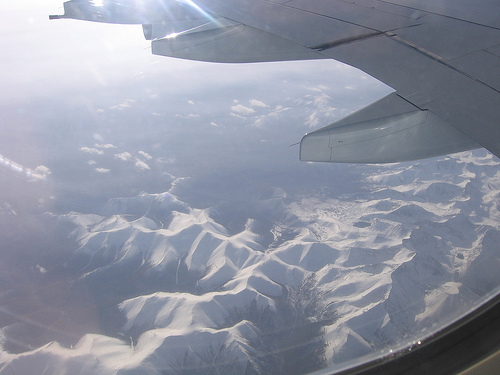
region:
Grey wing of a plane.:
[62, 2, 498, 164]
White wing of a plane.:
[52, 0, 499, 165]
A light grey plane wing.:
[50, 2, 498, 168]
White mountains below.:
[11, 143, 497, 373]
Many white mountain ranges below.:
[27, 128, 489, 373]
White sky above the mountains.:
[2, 2, 178, 92]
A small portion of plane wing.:
[45, 2, 498, 163]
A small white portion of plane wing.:
[47, 3, 498, 167]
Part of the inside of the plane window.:
[349, 295, 499, 372]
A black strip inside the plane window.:
[325, 295, 499, 373]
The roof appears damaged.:
[301, 18, 398, 62]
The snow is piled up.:
[94, 211, 295, 373]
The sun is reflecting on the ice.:
[82, 2, 196, 42]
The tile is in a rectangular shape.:
[316, 27, 498, 146]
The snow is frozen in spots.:
[149, 45, 400, 162]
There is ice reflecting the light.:
[57, 2, 218, 44]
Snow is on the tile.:
[5, 0, 498, 330]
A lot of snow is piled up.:
[5, 4, 493, 374]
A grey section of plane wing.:
[49, 3, 499, 173]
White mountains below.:
[28, 161, 465, 373]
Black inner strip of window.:
[338, 299, 498, 374]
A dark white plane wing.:
[50, 1, 498, 165]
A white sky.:
[0, 3, 177, 96]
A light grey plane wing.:
[49, 1, 499, 163]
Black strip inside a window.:
[340, 297, 497, 372]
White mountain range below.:
[26, 129, 498, 373]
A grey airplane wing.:
[50, 1, 498, 166]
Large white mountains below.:
[82, 179, 475, 372]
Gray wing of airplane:
[65, 5, 498, 164]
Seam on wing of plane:
[390, 31, 498, 102]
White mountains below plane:
[180, 220, 317, 295]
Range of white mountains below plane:
[5, 195, 316, 371]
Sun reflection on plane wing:
[85, 2, 230, 32]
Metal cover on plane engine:
[291, 92, 481, 158]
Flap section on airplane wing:
[227, 0, 375, 41]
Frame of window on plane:
[327, 282, 497, 367]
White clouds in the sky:
[225, 90, 271, 120]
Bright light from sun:
[12, 3, 155, 85]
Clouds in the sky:
[106, 105, 208, 202]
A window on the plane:
[109, 160, 214, 245]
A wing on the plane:
[211, 0, 419, 186]